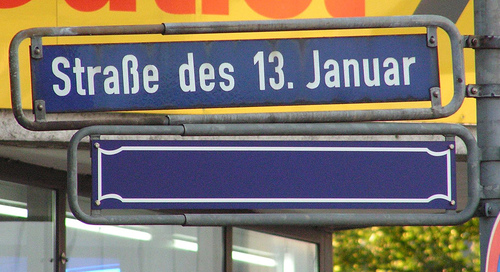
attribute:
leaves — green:
[335, 217, 482, 270]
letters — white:
[307, 46, 412, 90]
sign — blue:
[16, 33, 449, 104]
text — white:
[44, 40, 429, 110]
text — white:
[53, 53, 161, 97]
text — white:
[46, 40, 424, 97]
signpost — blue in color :
[68, 119, 489, 223]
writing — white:
[41, 44, 425, 99]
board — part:
[228, 163, 284, 192]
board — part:
[86, 138, 456, 217]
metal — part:
[308, 210, 344, 226]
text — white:
[52, 49, 417, 97]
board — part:
[88, 135, 457, 211]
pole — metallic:
[470, 7, 497, 262]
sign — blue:
[51, 27, 406, 125]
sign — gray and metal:
[30, 33, 440, 110]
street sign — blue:
[10, 18, 466, 112]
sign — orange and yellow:
[5, 4, 480, 125]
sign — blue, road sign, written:
[23, 35, 450, 120]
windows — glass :
[24, 225, 309, 272]